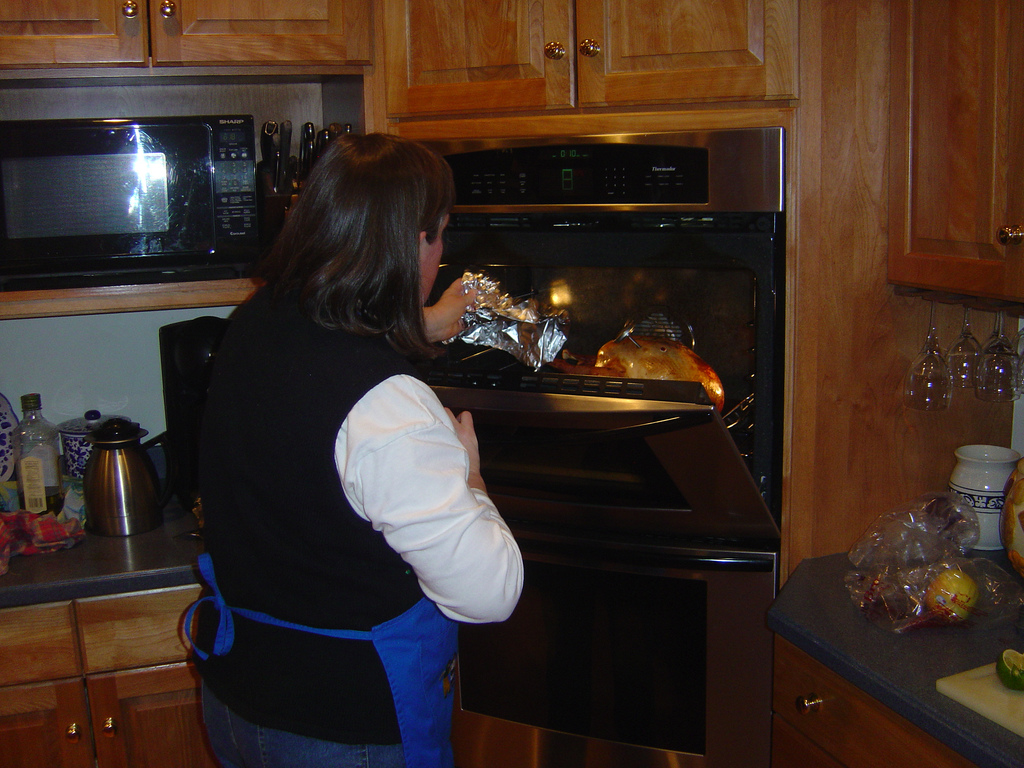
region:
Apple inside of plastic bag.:
[922, 555, 998, 628]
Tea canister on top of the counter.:
[82, 410, 166, 543]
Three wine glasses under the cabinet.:
[896, 274, 1021, 417]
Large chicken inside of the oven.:
[597, 329, 716, 396]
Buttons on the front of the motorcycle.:
[6, 141, 314, 285]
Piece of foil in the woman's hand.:
[454, 259, 578, 380]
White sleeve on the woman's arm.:
[373, 384, 454, 505]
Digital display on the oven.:
[539, 129, 597, 165]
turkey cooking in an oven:
[593, 325, 726, 412]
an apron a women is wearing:
[179, 544, 464, 761]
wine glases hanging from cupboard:
[900, 304, 1022, 412]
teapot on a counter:
[82, 412, 175, 543]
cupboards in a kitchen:
[370, 3, 805, 143]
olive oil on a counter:
[15, 385, 58, 519]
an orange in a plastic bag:
[919, 562, 986, 627]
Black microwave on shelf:
[2, 113, 256, 290]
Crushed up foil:
[458, 272, 569, 375]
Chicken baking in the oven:
[547, 331, 751, 393]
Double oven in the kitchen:
[441, 125, 795, 764]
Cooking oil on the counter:
[12, 388, 67, 516]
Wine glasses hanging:
[906, 300, 1023, 411]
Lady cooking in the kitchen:
[189, 121, 534, 767]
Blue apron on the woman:
[179, 554, 494, 764]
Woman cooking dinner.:
[202, 131, 539, 765]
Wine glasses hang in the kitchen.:
[890, 279, 1021, 419]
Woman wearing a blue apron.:
[194, 122, 515, 765]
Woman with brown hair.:
[202, 125, 526, 765]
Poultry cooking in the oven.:
[574, 308, 740, 438]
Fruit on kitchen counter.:
[921, 554, 980, 625]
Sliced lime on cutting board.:
[934, 640, 1020, 717]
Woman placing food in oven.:
[194, 134, 523, 763]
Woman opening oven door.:
[207, 122, 533, 765]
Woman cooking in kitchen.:
[194, 128, 517, 765]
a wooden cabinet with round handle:
[879, 4, 1022, 306]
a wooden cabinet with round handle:
[84, 663, 231, 765]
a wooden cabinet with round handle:
[0, 674, 94, 766]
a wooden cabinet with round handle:
[572, 6, 811, 112]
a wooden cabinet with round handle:
[378, 4, 575, 125]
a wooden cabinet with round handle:
[151, 0, 376, 66]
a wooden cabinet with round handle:
[2, 0, 149, 67]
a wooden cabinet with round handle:
[388, 0, 812, 127]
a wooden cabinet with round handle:
[0, 0, 370, 80]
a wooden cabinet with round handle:
[0, 658, 215, 764]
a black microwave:
[1, 104, 270, 289]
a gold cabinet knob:
[99, 714, 122, 731]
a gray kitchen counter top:
[763, 536, 1019, 759]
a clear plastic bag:
[838, 491, 1015, 635]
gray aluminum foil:
[456, 264, 570, 366]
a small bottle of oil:
[20, 385, 74, 526]